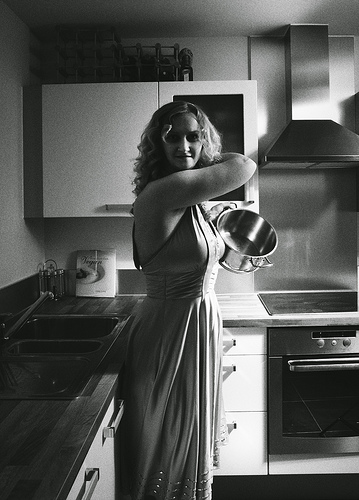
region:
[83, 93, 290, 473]
a lady wearing a formal dress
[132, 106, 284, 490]
a lady in dress holding a pot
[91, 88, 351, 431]
a lady in the kitchen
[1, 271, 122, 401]
a sink with a faucet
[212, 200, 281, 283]
a stainless steel pot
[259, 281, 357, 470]
a stainless steel oven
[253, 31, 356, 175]
a vent hood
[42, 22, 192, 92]
a wine rack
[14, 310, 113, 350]
a sink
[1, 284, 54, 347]
a stainless steel faucet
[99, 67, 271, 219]
woman's arm in front of neck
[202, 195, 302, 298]
woman holding a pot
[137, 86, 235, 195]
woman's hair is curly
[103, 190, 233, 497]
woman wearing a dress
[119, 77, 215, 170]
woman's hair is blonde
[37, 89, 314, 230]
the cabinets are white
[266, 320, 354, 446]
the oven is silver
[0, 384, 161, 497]
counter top made of wood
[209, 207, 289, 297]
the pot is silver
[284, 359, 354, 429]
window of oven is black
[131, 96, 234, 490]
A woman in a dress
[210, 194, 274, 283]
A put being held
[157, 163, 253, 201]
A womans upper arm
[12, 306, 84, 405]
An empty steel sink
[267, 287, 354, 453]
A stove and oven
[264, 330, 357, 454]
A closed oven door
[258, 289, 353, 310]
An empty black stove top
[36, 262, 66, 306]
Various flavoring spices salt pepper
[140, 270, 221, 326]
A womans mid waist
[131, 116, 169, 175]
A womans blonde hair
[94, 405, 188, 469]
cabinet handle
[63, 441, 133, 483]
cabinet handle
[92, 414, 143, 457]
cabinet handle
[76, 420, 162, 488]
cabinet handle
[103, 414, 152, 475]
cabinet handle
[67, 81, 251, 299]
woman holding pot in kitchen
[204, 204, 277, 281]
metal pot in hand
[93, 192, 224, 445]
dress on woman in kitchen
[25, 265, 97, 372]
metal sink behind woman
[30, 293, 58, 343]
metal sink spout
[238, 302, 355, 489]
oven in the kitchen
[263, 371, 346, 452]
glass door on front of oven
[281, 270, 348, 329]
stove top in kitchen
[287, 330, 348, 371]
knobs for stove in kitchen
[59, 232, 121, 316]
cook book in back of counter